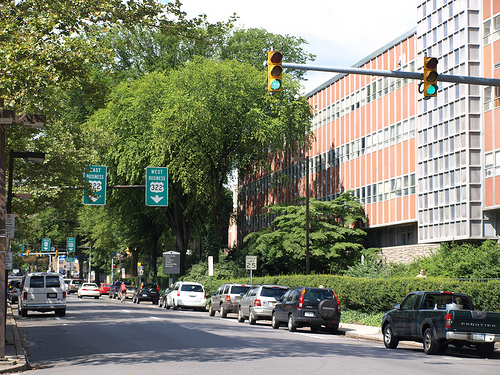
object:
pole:
[296, 62, 388, 82]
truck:
[380, 290, 500, 357]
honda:
[271, 286, 342, 337]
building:
[236, 0, 497, 265]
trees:
[83, 56, 316, 275]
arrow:
[149, 194, 164, 204]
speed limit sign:
[245, 255, 257, 270]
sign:
[143, 166, 170, 206]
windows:
[373, 184, 376, 195]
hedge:
[199, 273, 498, 326]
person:
[119, 280, 127, 302]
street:
[9, 290, 499, 374]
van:
[20, 273, 68, 318]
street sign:
[267, 51, 289, 96]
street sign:
[423, 57, 440, 101]